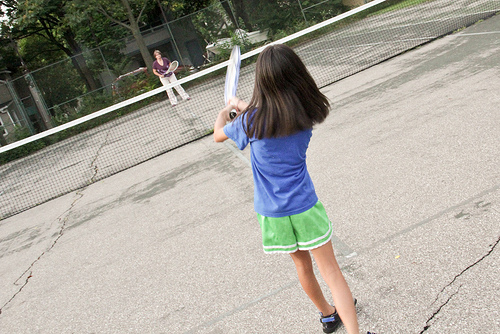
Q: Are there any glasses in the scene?
A: No, there are no glasses.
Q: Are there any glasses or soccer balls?
A: No, there are no glasses or soccer balls.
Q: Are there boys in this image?
A: No, there are no boys.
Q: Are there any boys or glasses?
A: No, there are no boys or glasses.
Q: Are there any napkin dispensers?
A: No, there are no napkin dispensers.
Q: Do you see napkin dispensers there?
A: No, there are no napkin dispensers.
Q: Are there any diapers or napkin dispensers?
A: No, there are no napkin dispensers or diapers.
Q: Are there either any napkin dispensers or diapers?
A: No, there are no napkin dispensers or diapers.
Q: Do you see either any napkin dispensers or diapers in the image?
A: No, there are no napkin dispensers or diapers.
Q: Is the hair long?
A: Yes, the hair is long.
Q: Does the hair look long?
A: Yes, the hair is long.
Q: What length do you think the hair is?
A: The hair is long.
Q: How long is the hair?
A: The hair is long.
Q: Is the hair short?
A: No, the hair is long.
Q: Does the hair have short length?
A: No, the hair is long.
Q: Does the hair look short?
A: No, the hair is long.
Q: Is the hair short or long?
A: The hair is long.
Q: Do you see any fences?
A: Yes, there is a fence.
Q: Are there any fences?
A: Yes, there is a fence.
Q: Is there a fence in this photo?
A: Yes, there is a fence.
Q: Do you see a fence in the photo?
A: Yes, there is a fence.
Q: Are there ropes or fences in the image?
A: Yes, there is a fence.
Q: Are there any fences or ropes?
A: Yes, there is a fence.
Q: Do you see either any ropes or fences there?
A: Yes, there is a fence.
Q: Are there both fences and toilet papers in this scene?
A: No, there is a fence but no toilet papers.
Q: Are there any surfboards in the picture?
A: No, there are no surfboards.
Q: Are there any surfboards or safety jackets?
A: No, there are no surfboards or safety jackets.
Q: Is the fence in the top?
A: Yes, the fence is in the top of the image.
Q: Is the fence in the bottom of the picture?
A: No, the fence is in the top of the image.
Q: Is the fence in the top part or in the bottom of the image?
A: The fence is in the top of the image.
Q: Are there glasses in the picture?
A: No, there are no glasses.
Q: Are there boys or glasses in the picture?
A: No, there are no glasses or boys.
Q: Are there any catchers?
A: No, there are no catchers.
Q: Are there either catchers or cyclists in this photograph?
A: No, there are no catchers or cyclists.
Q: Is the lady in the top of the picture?
A: Yes, the lady is in the top of the image.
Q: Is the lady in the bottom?
A: No, the lady is in the top of the image.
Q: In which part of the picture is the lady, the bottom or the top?
A: The lady is in the top of the image.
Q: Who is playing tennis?
A: The lady is playing tennis.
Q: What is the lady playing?
A: The lady is playing tennis.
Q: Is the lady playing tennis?
A: Yes, the lady is playing tennis.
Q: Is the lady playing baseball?
A: No, the lady is playing tennis.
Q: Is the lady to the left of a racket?
A: Yes, the lady is to the left of a racket.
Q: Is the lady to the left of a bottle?
A: No, the lady is to the left of a racket.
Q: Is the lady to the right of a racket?
A: No, the lady is to the left of a racket.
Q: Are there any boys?
A: No, there are no boys.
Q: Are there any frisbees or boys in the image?
A: No, there are no boys or frisbees.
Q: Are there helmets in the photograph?
A: No, there are no helmets.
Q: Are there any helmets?
A: No, there are no helmets.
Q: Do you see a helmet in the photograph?
A: No, there are no helmets.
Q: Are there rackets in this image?
A: Yes, there is a racket.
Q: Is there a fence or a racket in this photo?
A: Yes, there is a racket.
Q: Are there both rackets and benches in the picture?
A: No, there is a racket but no benches.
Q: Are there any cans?
A: No, there are no cans.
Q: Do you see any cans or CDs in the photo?
A: No, there are no cans or cds.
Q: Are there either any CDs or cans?
A: No, there are no cans or cds.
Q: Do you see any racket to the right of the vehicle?
A: Yes, there is a racket to the right of the vehicle.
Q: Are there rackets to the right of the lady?
A: Yes, there is a racket to the right of the lady.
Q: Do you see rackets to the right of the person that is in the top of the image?
A: Yes, there is a racket to the right of the lady.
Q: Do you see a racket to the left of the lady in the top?
A: No, the racket is to the right of the lady.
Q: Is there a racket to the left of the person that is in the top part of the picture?
A: No, the racket is to the right of the lady.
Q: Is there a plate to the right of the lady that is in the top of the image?
A: No, there is a racket to the right of the lady.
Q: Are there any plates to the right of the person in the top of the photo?
A: No, there is a racket to the right of the lady.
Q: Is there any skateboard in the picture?
A: No, there are no skateboards.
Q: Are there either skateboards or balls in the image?
A: No, there are no skateboards or balls.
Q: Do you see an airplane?
A: No, there are no airplanes.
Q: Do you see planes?
A: No, there are no planes.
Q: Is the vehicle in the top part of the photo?
A: Yes, the vehicle is in the top of the image.